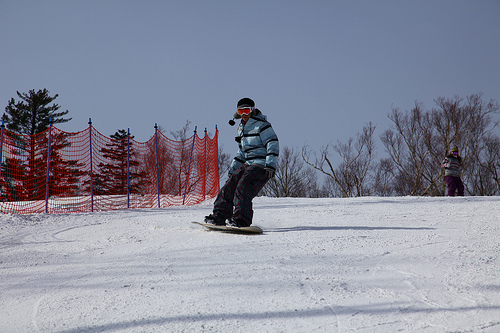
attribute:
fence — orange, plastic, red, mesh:
[95, 149, 128, 212]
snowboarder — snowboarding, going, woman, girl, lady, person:
[207, 98, 277, 232]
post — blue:
[126, 129, 130, 212]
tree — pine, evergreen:
[11, 98, 51, 125]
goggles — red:
[239, 107, 252, 115]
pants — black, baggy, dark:
[212, 172, 259, 221]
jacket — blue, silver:
[237, 118, 271, 167]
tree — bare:
[400, 120, 431, 187]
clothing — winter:
[245, 145, 265, 197]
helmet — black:
[240, 97, 251, 103]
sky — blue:
[192, 15, 333, 34]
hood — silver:
[254, 115, 263, 120]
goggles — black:
[455, 152, 459, 154]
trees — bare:
[404, 98, 478, 140]